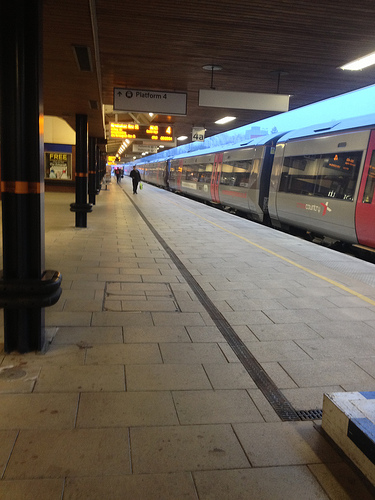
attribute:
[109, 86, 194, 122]
sign — black, white, black &white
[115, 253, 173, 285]
bricks — gray, tan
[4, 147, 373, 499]
sidewalk — brick, gray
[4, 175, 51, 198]
ring — copper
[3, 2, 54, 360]
pole — black, support beam, metal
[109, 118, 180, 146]
sign — lit up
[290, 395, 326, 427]
drain — metal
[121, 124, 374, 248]
subway train — silver, red, long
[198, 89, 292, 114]
sign — white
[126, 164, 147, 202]
person — walking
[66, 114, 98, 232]
pole — black, metal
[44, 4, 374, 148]
ceiling — wooden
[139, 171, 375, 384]
line — yellow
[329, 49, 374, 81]
light — rectangular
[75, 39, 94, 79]
vent — metal